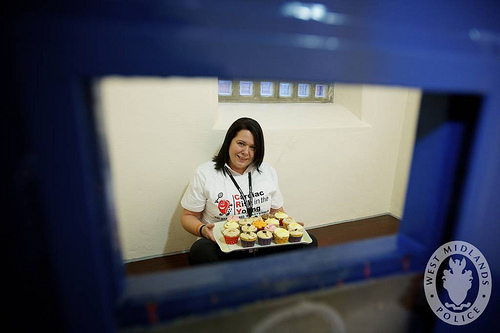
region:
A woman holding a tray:
[181, 114, 327, 255]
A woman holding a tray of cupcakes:
[190, 118, 313, 274]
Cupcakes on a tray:
[218, 214, 314, 278]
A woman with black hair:
[204, 119, 292, 187]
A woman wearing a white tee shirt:
[193, 118, 287, 217]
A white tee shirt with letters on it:
[197, 179, 280, 212]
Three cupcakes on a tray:
[242, 222, 270, 246]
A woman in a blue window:
[69, 55, 479, 288]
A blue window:
[61, 34, 481, 270]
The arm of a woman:
[164, 182, 217, 252]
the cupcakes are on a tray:
[207, 212, 332, 255]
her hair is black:
[217, 118, 276, 168]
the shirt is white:
[220, 169, 275, 214]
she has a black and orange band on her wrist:
[190, 220, 215, 245]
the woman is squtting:
[191, 120, 311, 250]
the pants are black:
[180, 243, 333, 268]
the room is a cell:
[106, 97, 425, 284]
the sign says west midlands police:
[421, 237, 494, 332]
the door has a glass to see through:
[58, 83, 489, 329]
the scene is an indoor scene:
[18, 69, 472, 300]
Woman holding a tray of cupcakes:
[174, 99, 319, 271]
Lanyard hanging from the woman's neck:
[217, 152, 263, 219]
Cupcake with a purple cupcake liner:
[239, 227, 258, 253]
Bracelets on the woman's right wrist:
[194, 216, 208, 243]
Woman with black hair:
[211, 113, 269, 176]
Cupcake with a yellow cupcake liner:
[269, 225, 291, 245]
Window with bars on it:
[207, 80, 349, 113]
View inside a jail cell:
[35, 7, 484, 318]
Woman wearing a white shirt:
[185, 111, 320, 263]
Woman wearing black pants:
[167, 113, 339, 294]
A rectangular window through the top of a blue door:
[1, 0, 499, 331]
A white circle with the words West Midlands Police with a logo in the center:
[410, 240, 499, 324]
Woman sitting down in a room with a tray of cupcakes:
[183, 118, 320, 254]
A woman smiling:
[213, 110, 277, 177]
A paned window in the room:
[216, 78, 356, 117]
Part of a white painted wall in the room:
[116, 77, 183, 265]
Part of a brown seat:
[308, 206, 400, 241]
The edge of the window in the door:
[53, 20, 498, 315]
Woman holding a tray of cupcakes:
[206, 210, 319, 252]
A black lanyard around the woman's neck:
[223, 166, 261, 213]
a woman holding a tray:
[152, 111, 339, 274]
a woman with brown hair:
[212, 123, 278, 185]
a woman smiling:
[176, 129, 277, 198]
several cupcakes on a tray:
[212, 211, 315, 256]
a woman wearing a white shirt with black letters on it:
[188, 112, 280, 223]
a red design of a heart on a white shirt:
[209, 187, 233, 224]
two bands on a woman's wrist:
[193, 217, 215, 245]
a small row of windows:
[204, 72, 342, 119]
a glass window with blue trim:
[66, 48, 489, 298]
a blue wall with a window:
[1, 72, 483, 322]